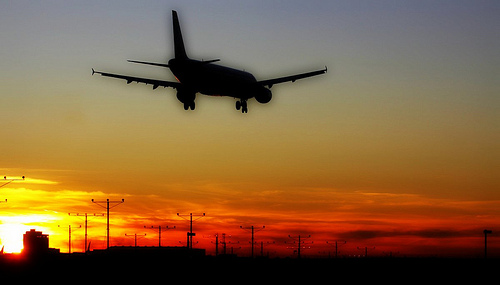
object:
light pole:
[92, 195, 126, 251]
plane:
[89, 9, 328, 114]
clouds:
[0, 173, 499, 257]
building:
[22, 228, 50, 258]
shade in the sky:
[346, 224, 466, 242]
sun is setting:
[1, 209, 57, 255]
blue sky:
[1, 1, 496, 77]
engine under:
[255, 86, 271, 105]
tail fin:
[172, 9, 189, 60]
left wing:
[89, 69, 175, 90]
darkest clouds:
[335, 201, 495, 254]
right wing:
[256, 65, 327, 87]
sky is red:
[0, 195, 216, 250]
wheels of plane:
[233, 98, 246, 111]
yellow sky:
[88, 176, 277, 226]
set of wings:
[93, 58, 329, 89]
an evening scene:
[1, 1, 499, 284]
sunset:
[0, 174, 499, 255]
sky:
[0, 0, 499, 207]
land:
[0, 245, 499, 284]